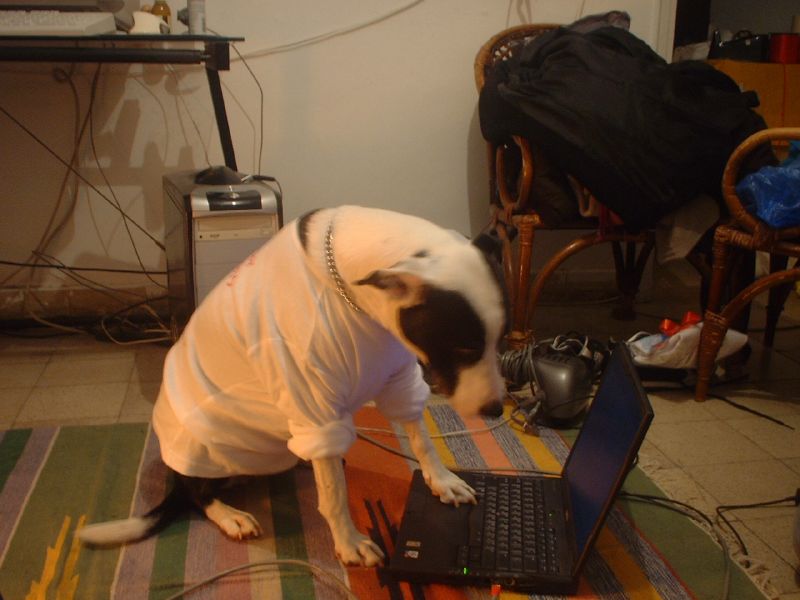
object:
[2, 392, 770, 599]
area rug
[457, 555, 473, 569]
button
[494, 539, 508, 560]
button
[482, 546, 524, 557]
button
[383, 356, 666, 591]
laptop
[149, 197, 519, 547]
dog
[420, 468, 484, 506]
paw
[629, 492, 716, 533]
cords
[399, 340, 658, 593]
computer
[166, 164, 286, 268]
case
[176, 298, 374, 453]
shirt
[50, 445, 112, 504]
rug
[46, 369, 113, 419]
floor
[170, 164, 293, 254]
drive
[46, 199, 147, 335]
wires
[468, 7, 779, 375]
chairs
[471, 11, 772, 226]
miscellaneous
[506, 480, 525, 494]
key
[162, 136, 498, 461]
dog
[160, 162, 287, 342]
computer tower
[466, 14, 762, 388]
chair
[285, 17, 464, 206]
wall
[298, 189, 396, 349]
collar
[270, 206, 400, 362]
neck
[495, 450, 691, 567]
tile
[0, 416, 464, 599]
ground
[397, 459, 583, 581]
keyboard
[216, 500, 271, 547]
paw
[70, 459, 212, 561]
tail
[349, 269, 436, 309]
ear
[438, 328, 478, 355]
eye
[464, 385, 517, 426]
nose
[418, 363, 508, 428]
mouth